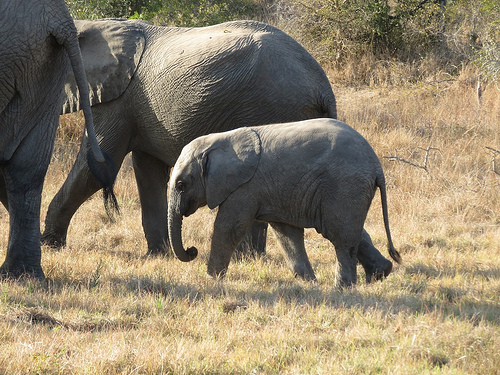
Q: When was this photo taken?
A: During the day.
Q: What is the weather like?
A: Sunny.